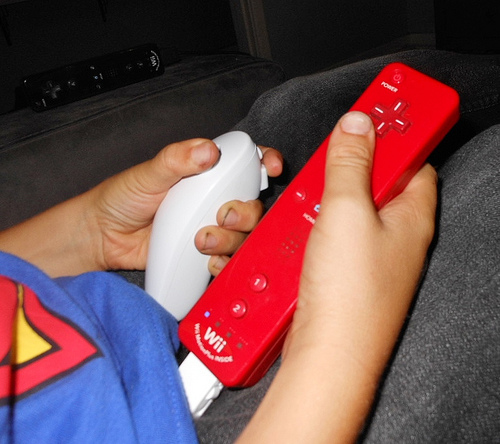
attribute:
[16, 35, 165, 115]
wii remote — black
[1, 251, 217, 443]
shirt — blue, bright blue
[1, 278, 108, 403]
superman logo — red, yellow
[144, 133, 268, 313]
wii remote — white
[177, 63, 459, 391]
wii remote — red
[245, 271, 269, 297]
1 botton — round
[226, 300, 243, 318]
2 button — round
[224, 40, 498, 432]
jeans — gray, blue denim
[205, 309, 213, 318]
light — white